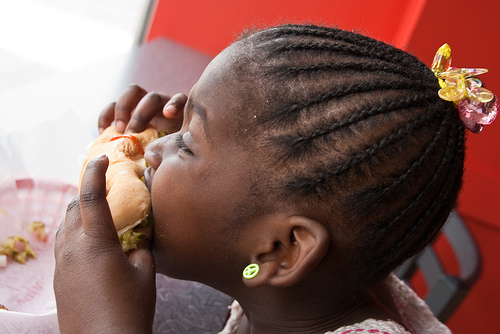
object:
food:
[81, 125, 178, 258]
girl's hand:
[21, 148, 164, 333]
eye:
[173, 126, 201, 159]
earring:
[242, 260, 261, 280]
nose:
[143, 125, 180, 171]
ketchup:
[105, 126, 146, 156]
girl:
[55, 16, 500, 333]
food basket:
[0, 173, 94, 324]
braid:
[265, 78, 437, 122]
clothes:
[324, 270, 445, 334]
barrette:
[431, 43, 498, 134]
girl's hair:
[209, 23, 500, 260]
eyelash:
[173, 128, 194, 157]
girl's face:
[125, 16, 279, 300]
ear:
[245, 214, 330, 291]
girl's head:
[123, 22, 492, 313]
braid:
[265, 61, 430, 84]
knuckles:
[79, 186, 105, 203]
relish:
[115, 214, 151, 254]